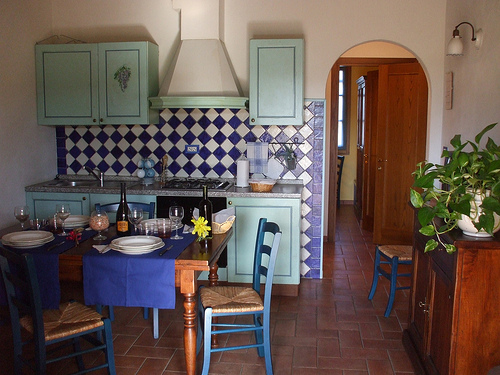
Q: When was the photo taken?
A: Daytime.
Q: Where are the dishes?
A: Table.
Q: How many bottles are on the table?
A: Two.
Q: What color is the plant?
A: Green.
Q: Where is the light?
A: Wall.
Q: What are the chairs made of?
A: Wood.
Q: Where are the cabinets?
A: Wall.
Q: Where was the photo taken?
A: Kitchen.